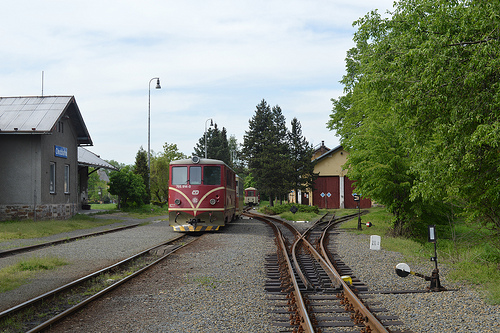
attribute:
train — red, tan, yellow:
[165, 155, 245, 233]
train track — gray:
[265, 215, 364, 296]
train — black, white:
[241, 184, 262, 205]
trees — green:
[326, 6, 499, 229]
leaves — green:
[380, 49, 469, 119]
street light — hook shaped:
[142, 75, 160, 179]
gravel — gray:
[198, 262, 263, 332]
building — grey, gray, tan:
[1, 94, 93, 218]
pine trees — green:
[247, 101, 312, 203]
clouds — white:
[83, 5, 241, 76]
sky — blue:
[1, 1, 347, 133]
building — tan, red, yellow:
[307, 140, 363, 211]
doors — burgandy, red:
[306, 176, 371, 209]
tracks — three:
[248, 198, 374, 279]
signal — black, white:
[392, 261, 412, 280]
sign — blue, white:
[55, 146, 70, 158]